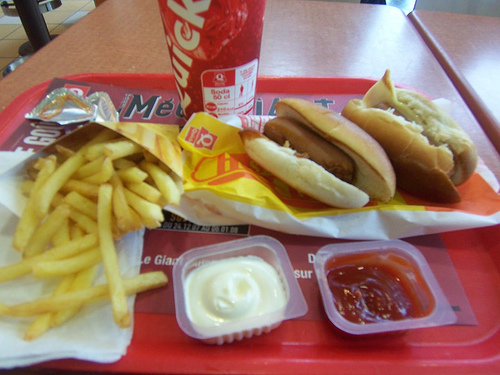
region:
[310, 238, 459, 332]
a small container of ketchup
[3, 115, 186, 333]
french fries in a small bag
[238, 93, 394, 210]
a hotdog in a bun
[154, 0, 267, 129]
the cup is red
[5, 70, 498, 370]
the tray is red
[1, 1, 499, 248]
the table is brown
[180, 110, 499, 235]
the bag is yellow and orange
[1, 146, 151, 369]
napkins under the french fries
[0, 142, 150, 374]
napkins are white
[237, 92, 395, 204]
the bun is brown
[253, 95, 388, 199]
hot dog in a bun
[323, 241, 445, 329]
packet of ketchup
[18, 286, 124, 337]
french fries on a napkin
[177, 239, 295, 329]
small packet of mayonnaise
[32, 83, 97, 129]
top of ketchup packet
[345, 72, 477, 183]
hot dog bun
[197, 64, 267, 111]
tag on soda cup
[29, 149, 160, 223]
pack of french fries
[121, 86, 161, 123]
letter M on a tray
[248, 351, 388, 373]
edge of a red tray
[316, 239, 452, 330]
a plastic container of ketchup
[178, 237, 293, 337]
a plastic container of mayonnaise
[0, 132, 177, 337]
an order of french fries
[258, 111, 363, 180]
a hot dog on a bun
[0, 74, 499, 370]
a red plastic tray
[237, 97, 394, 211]
a hot dog bun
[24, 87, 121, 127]
tops off plastic containers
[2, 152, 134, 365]
a pile of white napkins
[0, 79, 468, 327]
a paper tray liner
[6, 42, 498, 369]
a fast food lunch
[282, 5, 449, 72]
The table is made of wood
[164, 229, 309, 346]
The container of ranch on the table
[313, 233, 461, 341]
The container on the table is ketchup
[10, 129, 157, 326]
The french fries on the tray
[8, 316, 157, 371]
The napkin on the table is the color white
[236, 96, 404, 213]
The hot dog on tray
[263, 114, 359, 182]
The meat to the hot dog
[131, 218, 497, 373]
The tray is the color red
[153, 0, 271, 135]
A beverage sitting on the tray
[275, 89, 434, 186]
The white bread holding the hot dog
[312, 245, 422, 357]
small clear cup of ketchup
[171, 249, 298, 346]
white tub of mayo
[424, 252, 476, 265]
red piece of paper on tray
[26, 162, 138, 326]
bunch of yellow golden fries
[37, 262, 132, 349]
white napkin on tray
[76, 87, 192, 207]
yellow small bag for fries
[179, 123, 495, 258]
wrapper for hotdogs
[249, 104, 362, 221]
toasted bun wth corn dog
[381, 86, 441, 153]
relish on corn dog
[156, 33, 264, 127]
red and white cup